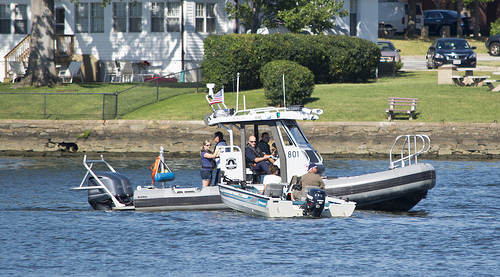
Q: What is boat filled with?
A: Many people.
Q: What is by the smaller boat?
A: Boat on water.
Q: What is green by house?
A: A hedge.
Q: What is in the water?
A: Two boats.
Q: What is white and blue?
A: Fishing boat.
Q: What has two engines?
A: Police boat.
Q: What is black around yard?
A: A fence.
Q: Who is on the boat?
A: Six people.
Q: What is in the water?
A: A boat.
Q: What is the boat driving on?
A: Water.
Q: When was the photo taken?
A: During the day.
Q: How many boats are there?
A: Two.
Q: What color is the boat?
A: White.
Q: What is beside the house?
A: Cars.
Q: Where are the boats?
A: In the water.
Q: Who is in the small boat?
A: A man.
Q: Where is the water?
A: In front of the house.